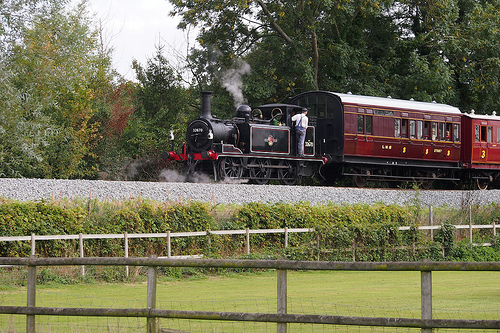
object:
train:
[161, 90, 500, 190]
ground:
[3, 217, 52, 257]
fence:
[0, 223, 500, 333]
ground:
[350, 227, 378, 255]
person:
[446, 131, 452, 141]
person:
[432, 123, 435, 141]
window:
[358, 108, 365, 133]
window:
[395, 118, 402, 138]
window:
[410, 120, 417, 140]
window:
[418, 120, 424, 140]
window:
[422, 114, 431, 140]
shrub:
[83, 202, 148, 242]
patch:
[217, 232, 249, 255]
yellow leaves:
[71, 93, 100, 147]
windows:
[358, 114, 364, 133]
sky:
[113, 33, 153, 56]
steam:
[217, 58, 253, 108]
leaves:
[112, 108, 129, 130]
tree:
[0, 0, 31, 180]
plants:
[305, 205, 375, 226]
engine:
[162, 91, 323, 186]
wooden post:
[419, 271, 431, 333]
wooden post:
[277, 268, 287, 332]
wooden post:
[146, 266, 157, 333]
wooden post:
[27, 265, 35, 333]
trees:
[468, 0, 500, 115]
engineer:
[291, 108, 308, 158]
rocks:
[0, 178, 500, 213]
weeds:
[0, 193, 500, 264]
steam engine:
[186, 91, 291, 160]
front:
[162, 90, 348, 185]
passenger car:
[161, 89, 463, 189]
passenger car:
[459, 109, 500, 191]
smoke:
[208, 47, 254, 107]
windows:
[365, 108, 374, 134]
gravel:
[1, 178, 500, 206]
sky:
[97, 3, 128, 14]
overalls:
[295, 115, 306, 155]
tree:
[113, 46, 160, 177]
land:
[321, 277, 407, 309]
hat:
[302, 107, 311, 110]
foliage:
[0, 192, 500, 261]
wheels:
[220, 157, 300, 186]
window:
[453, 123, 460, 142]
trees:
[166, 63, 183, 141]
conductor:
[291, 108, 309, 158]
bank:
[117, 180, 347, 241]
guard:
[162, 142, 218, 163]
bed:
[0, 179, 500, 208]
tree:
[44, 2, 78, 171]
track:
[0, 173, 500, 191]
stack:
[198, 91, 213, 119]